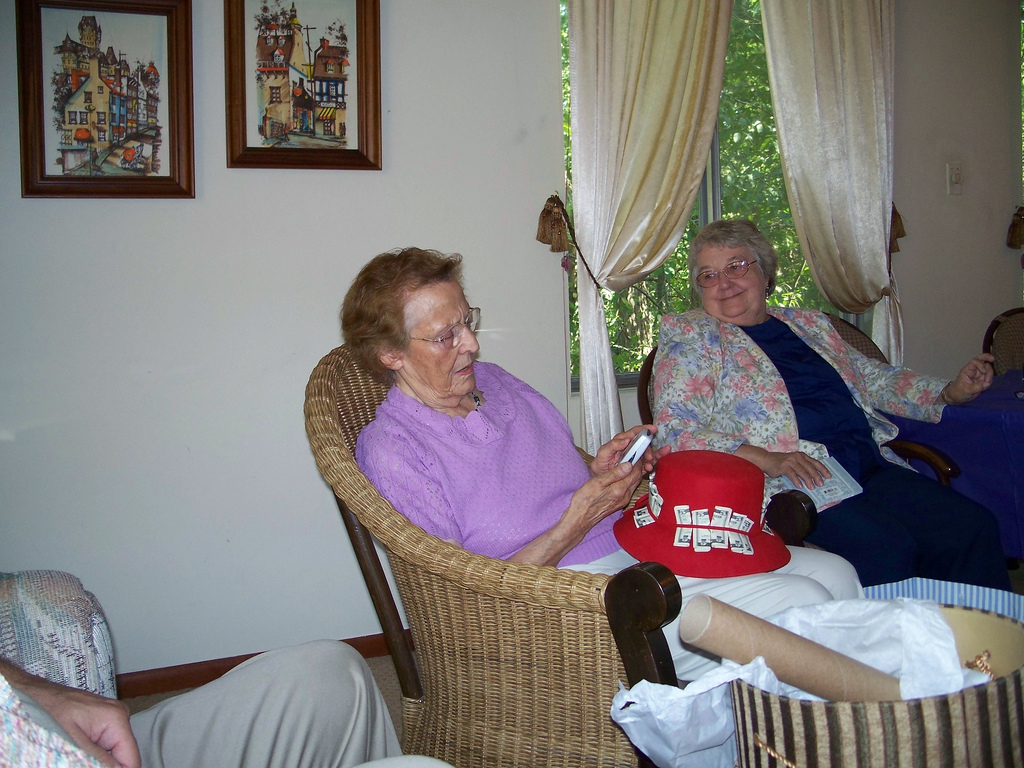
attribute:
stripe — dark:
[746, 691, 766, 765]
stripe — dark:
[765, 691, 781, 765]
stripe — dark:
[767, 703, 797, 754]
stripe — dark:
[798, 659, 819, 764]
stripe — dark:
[822, 705, 861, 764]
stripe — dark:
[841, 685, 874, 763]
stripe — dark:
[878, 698, 902, 762]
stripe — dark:
[896, 703, 922, 765]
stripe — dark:
[922, 695, 949, 765]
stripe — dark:
[964, 685, 991, 753]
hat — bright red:
[628, 442, 818, 567]